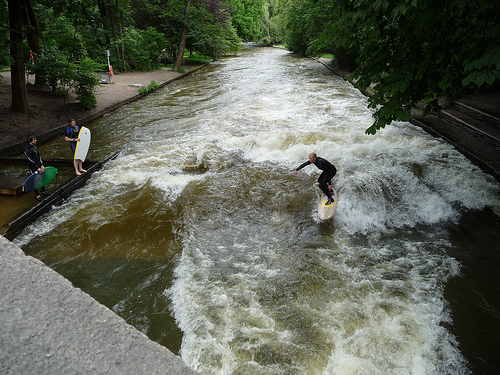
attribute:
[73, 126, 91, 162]
board — white, yellow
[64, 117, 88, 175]
person — standing, barefoot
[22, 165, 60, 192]
board — green, black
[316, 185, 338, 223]
surfboard — gray, white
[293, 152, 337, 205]
person — surfing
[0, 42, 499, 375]
water — moving, white, brown, fast, streaming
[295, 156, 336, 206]
wetsuit — black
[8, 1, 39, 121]
trunk — brown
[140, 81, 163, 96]
grass — tall